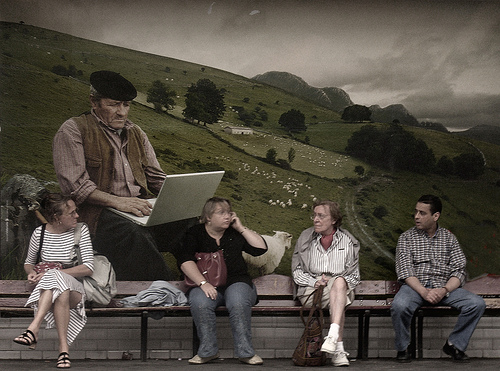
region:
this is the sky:
[276, 10, 458, 49]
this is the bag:
[291, 282, 328, 362]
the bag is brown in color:
[300, 330, 317, 367]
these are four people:
[18, 194, 485, 364]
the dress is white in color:
[48, 236, 68, 281]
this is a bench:
[101, 304, 170, 356]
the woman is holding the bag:
[179, 251, 228, 287]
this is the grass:
[151, 87, 267, 139]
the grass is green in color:
[9, 87, 40, 151]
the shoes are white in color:
[322, 339, 342, 351]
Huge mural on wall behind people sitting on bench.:
[9, 13, 499, 275]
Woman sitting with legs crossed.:
[290, 203, 361, 358]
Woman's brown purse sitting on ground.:
[290, 278, 337, 368]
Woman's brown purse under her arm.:
[174, 243, 233, 298]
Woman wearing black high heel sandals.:
[12, 324, 74, 369]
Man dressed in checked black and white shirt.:
[390, 225, 470, 297]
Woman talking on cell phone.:
[202, 199, 267, 257]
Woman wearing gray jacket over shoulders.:
[289, 202, 369, 292]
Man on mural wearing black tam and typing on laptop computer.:
[46, 58, 223, 283]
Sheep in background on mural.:
[233, 156, 333, 213]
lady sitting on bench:
[10, 187, 115, 364]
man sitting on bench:
[385, 180, 497, 370]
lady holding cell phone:
[174, 197, 285, 369]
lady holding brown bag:
[293, 194, 369, 368]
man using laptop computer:
[53, 60, 233, 261]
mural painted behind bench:
[21, 64, 469, 318]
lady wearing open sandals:
[19, 189, 137, 367]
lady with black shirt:
[170, 194, 270, 368]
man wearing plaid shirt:
[380, 186, 483, 316]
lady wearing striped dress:
[13, 183, 135, 355]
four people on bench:
[16, 182, 486, 355]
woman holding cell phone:
[175, 197, 265, 298]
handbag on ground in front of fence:
[284, 291, 330, 369]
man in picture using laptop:
[53, 63, 227, 276]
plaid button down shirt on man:
[396, 225, 471, 298]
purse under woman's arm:
[176, 246, 228, 295]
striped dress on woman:
[11, 218, 100, 342]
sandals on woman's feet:
[11, 323, 91, 369]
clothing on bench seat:
[111, 273, 188, 318]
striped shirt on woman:
[291, 232, 357, 292]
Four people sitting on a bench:
[14, 185, 478, 357]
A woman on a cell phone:
[167, 179, 278, 369]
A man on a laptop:
[42, 59, 213, 227]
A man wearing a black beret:
[59, 60, 198, 240]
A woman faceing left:
[281, 175, 364, 369]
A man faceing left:
[388, 192, 468, 359]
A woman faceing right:
[14, 173, 121, 358]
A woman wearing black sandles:
[28, 187, 108, 368]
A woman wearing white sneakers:
[283, 191, 360, 361]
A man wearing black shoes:
[401, 178, 475, 366]